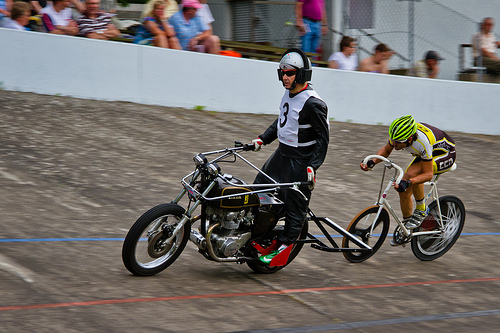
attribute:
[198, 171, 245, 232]
motorbike — black, standing, silver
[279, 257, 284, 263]
stirrup — red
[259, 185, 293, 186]
handlebar — unique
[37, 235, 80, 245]
line — blue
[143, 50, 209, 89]
stand — white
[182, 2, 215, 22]
person — watching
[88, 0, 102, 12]
person — watching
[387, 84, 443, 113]
barrier — white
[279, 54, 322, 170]
rider — working, pulling, riding, wearing, focused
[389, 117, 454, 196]
rider — riding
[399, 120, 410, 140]
helmet — green, striped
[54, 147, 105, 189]
ground — gray, brown